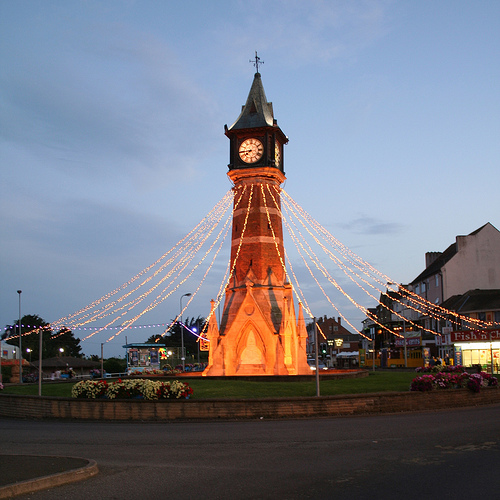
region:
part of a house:
[416, 363, 428, 378]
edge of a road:
[270, 450, 272, 458]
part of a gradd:
[264, 420, 274, 431]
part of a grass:
[146, 385, 155, 392]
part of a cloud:
[174, 300, 183, 317]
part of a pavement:
[64, 465, 75, 473]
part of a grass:
[287, 338, 291, 353]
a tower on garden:
[182, 40, 327, 381]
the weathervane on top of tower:
[247, 45, 267, 74]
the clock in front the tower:
[234, 135, 266, 164]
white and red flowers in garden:
[61, 365, 201, 413]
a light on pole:
[11, 282, 30, 383]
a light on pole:
[173, 285, 199, 371]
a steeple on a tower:
[214, 47, 299, 207]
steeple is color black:
[214, 45, 301, 195]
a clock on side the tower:
[270, 132, 285, 169]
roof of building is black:
[371, 212, 498, 307]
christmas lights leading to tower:
[10, 180, 495, 365]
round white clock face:
[236, 139, 269, 165]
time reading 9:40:
[237, 138, 265, 166]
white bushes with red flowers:
[72, 376, 191, 402]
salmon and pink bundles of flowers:
[409, 360, 497, 393]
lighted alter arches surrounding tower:
[197, 276, 318, 380]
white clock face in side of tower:
[272, 142, 287, 166]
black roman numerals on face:
[235, 135, 264, 167]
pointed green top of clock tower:
[225, 62, 295, 136]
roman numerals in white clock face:
[272, 140, 281, 165]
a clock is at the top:
[207, 110, 405, 292]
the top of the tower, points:
[218, 68, 382, 175]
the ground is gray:
[112, 422, 188, 491]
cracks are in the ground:
[157, 418, 210, 478]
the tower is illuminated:
[224, 273, 357, 429]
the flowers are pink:
[406, 333, 489, 418]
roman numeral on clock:
[245, 138, 255, 145]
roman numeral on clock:
[252, 136, 257, 144]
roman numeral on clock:
[253, 139, 263, 147]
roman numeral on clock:
[255, 144, 264, 154]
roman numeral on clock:
[253, 150, 263, 157]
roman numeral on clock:
[251, 153, 260, 162]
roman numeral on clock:
[246, 155, 255, 164]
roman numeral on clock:
[241, 154, 251, 164]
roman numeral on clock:
[236, 150, 249, 160]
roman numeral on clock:
[238, 142, 248, 152]